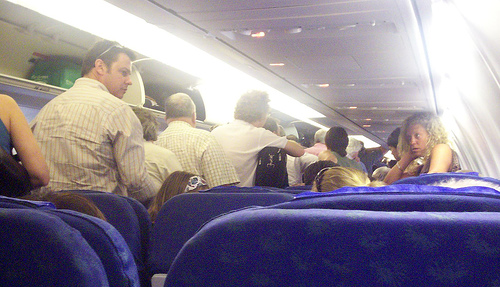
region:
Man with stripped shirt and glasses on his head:
[34, 39, 151, 194]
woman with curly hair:
[381, 110, 460, 180]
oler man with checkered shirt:
[155, 90, 239, 190]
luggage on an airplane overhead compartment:
[27, 51, 82, 84]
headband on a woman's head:
[180, 172, 206, 192]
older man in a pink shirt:
[305, 127, 326, 153]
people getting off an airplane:
[2, 40, 486, 198]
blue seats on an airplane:
[1, 173, 498, 285]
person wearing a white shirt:
[213, 87, 293, 185]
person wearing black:
[252, 115, 287, 191]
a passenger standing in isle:
[32, 35, 154, 201]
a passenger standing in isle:
[0, 88, 52, 189]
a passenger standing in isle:
[149, 90, 239, 186]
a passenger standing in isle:
[215, 88, 299, 180]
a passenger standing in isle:
[325, 122, 364, 166]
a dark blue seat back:
[166, 208, 495, 280]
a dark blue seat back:
[0, 203, 104, 285]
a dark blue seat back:
[44, 204, 137, 282]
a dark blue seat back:
[154, 187, 289, 266]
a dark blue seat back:
[49, 191, 141, 251]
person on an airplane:
[30, 38, 155, 217]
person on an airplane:
[152, 92, 248, 196]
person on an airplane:
[120, 105, 181, 187]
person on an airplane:
[143, 166, 208, 221]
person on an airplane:
[304, 160, 373, 199]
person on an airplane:
[207, 89, 312, 191]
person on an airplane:
[377, 108, 465, 189]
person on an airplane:
[315, 121, 368, 178]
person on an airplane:
[370, 160, 390, 185]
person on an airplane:
[0, 85, 55, 198]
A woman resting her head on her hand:
[383, 111, 456, 184]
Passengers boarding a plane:
[1, 35, 363, 187]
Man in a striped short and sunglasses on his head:
[33, 39, 162, 191]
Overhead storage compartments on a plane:
[1, 1, 318, 145]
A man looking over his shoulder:
[27, 39, 177, 195]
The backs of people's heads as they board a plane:
[133, 90, 370, 200]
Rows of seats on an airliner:
[0, 170, 499, 284]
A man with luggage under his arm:
[210, 88, 304, 188]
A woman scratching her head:
[384, 114, 472, 176]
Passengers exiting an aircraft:
[1, 39, 368, 182]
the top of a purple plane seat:
[179, 209, 499, 285]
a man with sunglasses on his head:
[38, 40, 156, 197]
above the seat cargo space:
[0, 3, 144, 108]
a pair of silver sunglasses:
[93, 40, 126, 60]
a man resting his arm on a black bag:
[218, 92, 295, 187]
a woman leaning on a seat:
[378, 109, 471, 181]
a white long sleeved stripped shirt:
[31, 78, 161, 197]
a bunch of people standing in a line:
[1, 35, 383, 183]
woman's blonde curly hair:
[393, 108, 448, 162]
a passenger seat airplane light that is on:
[239, 23, 271, 45]